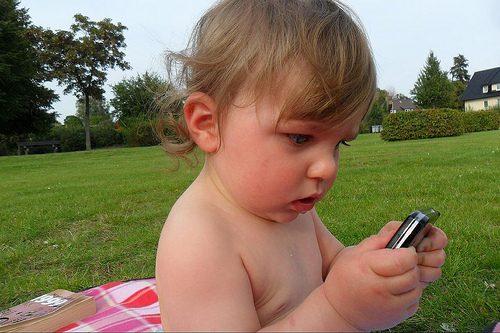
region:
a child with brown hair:
[156, 6, 448, 331]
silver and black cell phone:
[381, 206, 442, 268]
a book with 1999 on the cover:
[1, 286, 98, 331]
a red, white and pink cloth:
[42, 277, 161, 332]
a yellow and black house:
[458, 64, 499, 112]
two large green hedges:
[376, 106, 499, 143]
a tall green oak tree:
[36, 12, 131, 152]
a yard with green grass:
[0, 134, 499, 332]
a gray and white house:
[377, 95, 422, 115]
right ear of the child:
[184, 91, 226, 154]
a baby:
[133, 65, 325, 319]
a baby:
[263, 100, 434, 331]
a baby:
[154, 133, 270, 313]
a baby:
[234, 125, 347, 320]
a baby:
[223, 74, 302, 276]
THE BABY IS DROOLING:
[282, 196, 315, 221]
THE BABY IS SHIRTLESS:
[149, 0, 447, 332]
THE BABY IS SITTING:
[147, 1, 452, 331]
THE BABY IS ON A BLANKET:
[1, 275, 168, 331]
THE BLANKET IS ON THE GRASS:
[5, 275, 172, 332]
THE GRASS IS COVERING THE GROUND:
[2, 126, 497, 328]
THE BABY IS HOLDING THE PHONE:
[372, 196, 446, 273]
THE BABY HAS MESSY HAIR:
[141, 2, 384, 174]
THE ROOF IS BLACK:
[458, 62, 499, 104]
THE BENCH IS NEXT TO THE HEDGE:
[14, 134, 69, 173]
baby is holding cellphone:
[298, 160, 495, 286]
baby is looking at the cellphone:
[263, 104, 420, 242]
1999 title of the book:
[12, 275, 81, 330]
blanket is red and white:
[48, 257, 146, 328]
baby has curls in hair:
[133, 109, 191, 174]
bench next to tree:
[13, 128, 85, 157]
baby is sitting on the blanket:
[103, 218, 423, 320]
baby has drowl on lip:
[286, 190, 340, 237]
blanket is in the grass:
[59, 235, 200, 311]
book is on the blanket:
[27, 271, 118, 331]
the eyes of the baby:
[262, 112, 352, 156]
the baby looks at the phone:
[153, 2, 446, 331]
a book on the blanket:
[2, 282, 98, 332]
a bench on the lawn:
[12, 136, 66, 155]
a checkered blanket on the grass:
[86, 275, 143, 330]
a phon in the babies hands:
[369, 200, 458, 259]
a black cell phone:
[371, 198, 446, 273]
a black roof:
[461, 67, 498, 102]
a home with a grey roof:
[378, 92, 421, 114]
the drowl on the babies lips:
[298, 205, 312, 217]